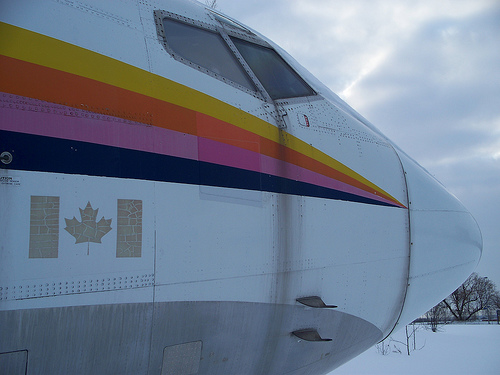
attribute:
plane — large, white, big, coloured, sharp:
[2, 1, 487, 375]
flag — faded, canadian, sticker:
[22, 190, 145, 265]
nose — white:
[400, 150, 486, 333]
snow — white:
[318, 310, 499, 374]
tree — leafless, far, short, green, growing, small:
[429, 273, 500, 326]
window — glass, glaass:
[223, 30, 322, 118]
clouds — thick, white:
[273, 2, 472, 109]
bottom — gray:
[2, 297, 390, 375]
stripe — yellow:
[1, 19, 401, 203]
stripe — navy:
[2, 129, 401, 209]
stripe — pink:
[3, 92, 399, 208]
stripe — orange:
[2, 55, 400, 203]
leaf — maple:
[62, 199, 115, 261]